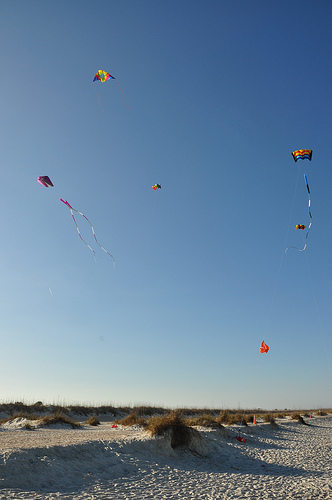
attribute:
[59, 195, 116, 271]
tail — long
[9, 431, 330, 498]
riverbank — sandy, grassy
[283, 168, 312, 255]
tail — long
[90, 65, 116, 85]
kite — rainbow colored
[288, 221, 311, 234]
kite — multicolored, parachute-shaped 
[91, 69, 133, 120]
kite — orange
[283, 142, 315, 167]
kite — multi-color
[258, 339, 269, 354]
kite — orange, low 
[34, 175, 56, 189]
kite — purple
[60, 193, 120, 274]
striped tail — pink, white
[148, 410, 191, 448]
grass — dark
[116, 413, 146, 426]
grass — dark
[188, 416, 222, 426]
grass — dark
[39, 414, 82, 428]
grass — dark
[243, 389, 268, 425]
cone — orange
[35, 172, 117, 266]
kite —  purple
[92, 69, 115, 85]
kite — triangular tie-dye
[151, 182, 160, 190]
kite — white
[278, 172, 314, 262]
tail — blue, black, white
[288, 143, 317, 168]
kite — multi-color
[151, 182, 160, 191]
kite — parachute-shaped, distance, rainbow-striped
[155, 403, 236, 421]
bush — wild, green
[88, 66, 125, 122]
kite — rainbow-colored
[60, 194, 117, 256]
ribbons — long striped 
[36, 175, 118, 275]
kite — pink, white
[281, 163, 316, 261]
tail — long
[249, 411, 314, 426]
caution cones — orange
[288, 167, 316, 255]
tail — blue, white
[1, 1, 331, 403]
sky — clear, blue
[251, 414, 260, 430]
item — orange